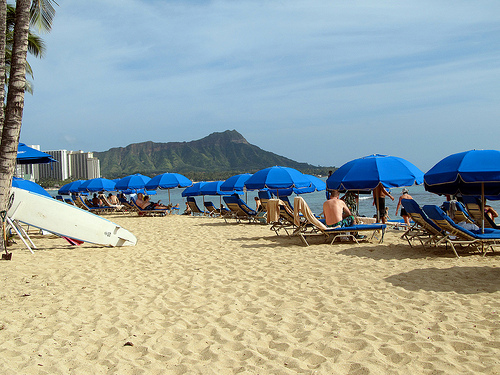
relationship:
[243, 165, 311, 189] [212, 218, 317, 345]
blue umbrella on beach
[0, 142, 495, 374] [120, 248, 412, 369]
beach has sand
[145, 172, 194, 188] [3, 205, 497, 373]
blue umbrella on beach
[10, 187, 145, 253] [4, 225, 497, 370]
surfboard on beach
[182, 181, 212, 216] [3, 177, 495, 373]
umbrella on beach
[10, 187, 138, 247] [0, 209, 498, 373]
surfboard on sand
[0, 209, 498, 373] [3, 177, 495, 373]
sand on beach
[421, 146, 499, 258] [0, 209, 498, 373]
blue umbrella in sand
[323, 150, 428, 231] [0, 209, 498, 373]
blue umbrella in sand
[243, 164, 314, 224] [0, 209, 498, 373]
blue umbrella in sand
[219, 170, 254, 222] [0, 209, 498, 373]
blue umbrella in sand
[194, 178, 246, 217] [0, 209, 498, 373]
blue umbrella in sand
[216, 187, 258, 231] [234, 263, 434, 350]
chair in sand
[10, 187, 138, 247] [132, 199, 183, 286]
surfboard on sand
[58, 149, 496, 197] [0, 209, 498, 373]
umbrellas in sand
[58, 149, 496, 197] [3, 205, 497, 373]
umbrellas on beach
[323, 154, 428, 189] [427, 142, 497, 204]
blue umbrella on umbrella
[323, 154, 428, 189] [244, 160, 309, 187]
blue umbrella on umbrella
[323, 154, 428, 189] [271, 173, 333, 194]
blue umbrella on umbrella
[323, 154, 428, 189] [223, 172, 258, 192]
blue umbrella on umbrella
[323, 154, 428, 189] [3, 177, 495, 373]
blue umbrella on beach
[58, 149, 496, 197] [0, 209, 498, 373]
umbrellas on sand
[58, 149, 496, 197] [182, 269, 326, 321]
umbrellas in sand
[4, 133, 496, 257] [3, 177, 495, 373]
umbrellas on beach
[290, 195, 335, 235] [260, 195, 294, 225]
towel on towel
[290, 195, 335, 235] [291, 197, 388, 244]
towel on chairs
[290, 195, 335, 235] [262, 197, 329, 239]
towel on chairs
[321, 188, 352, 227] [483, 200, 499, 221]
people on people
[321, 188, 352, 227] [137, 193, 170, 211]
people on people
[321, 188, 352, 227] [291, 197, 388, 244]
people on chairs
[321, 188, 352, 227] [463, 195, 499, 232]
people on chairs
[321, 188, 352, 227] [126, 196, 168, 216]
people on chairs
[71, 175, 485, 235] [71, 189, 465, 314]
people visiting beach